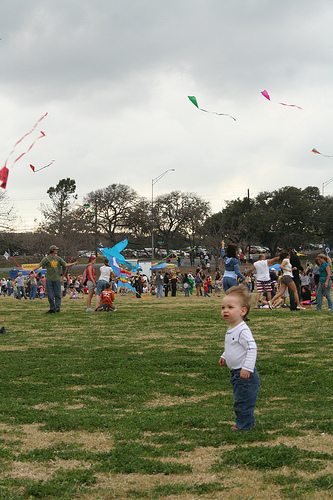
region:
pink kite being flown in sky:
[256, 87, 294, 118]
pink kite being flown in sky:
[18, 104, 49, 129]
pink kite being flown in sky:
[31, 122, 64, 151]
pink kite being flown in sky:
[36, 129, 53, 142]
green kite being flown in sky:
[177, 85, 198, 112]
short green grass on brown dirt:
[5, 408, 56, 454]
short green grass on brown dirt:
[74, 414, 137, 469]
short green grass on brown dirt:
[133, 386, 181, 421]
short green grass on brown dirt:
[114, 326, 156, 364]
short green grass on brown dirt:
[264, 428, 325, 481]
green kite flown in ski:
[183, 88, 206, 117]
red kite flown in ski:
[35, 123, 56, 150]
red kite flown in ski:
[34, 106, 51, 119]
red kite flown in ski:
[296, 133, 330, 162]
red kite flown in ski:
[252, 87, 278, 108]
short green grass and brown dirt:
[24, 338, 74, 377]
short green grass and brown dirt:
[98, 400, 157, 431]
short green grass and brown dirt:
[164, 364, 195, 414]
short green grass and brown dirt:
[270, 411, 322, 465]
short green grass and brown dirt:
[97, 455, 214, 477]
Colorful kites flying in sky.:
[171, 72, 329, 165]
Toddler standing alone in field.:
[214, 283, 262, 434]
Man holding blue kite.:
[27, 235, 140, 313]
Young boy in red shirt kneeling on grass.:
[95, 282, 116, 312]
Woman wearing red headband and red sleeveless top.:
[77, 252, 97, 287]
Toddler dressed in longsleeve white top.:
[216, 321, 259, 373]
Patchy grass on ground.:
[12, 413, 221, 499]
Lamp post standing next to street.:
[146, 163, 175, 257]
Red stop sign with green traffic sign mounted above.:
[153, 238, 167, 259]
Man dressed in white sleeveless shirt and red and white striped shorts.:
[246, 252, 277, 308]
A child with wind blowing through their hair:
[219, 285, 259, 431]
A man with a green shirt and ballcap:
[29, 245, 78, 313]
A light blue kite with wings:
[96, 239, 140, 280]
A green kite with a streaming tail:
[187, 95, 234, 120]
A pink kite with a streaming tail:
[261, 89, 301, 108]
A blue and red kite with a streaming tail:
[311, 147, 331, 157]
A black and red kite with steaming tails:
[0, 106, 47, 189]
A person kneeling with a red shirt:
[94, 282, 116, 311]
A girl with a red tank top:
[84, 256, 95, 311]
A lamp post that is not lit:
[150, 167, 173, 258]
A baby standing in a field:
[215, 285, 258, 429]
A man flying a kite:
[38, 246, 77, 314]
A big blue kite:
[97, 237, 140, 290]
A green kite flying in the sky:
[186, 93, 236, 123]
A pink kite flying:
[258, 88, 301, 108]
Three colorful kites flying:
[188, 86, 323, 155]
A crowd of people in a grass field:
[0, 242, 332, 312]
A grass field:
[0, 295, 332, 499]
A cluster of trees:
[0, 179, 332, 259]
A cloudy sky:
[0, 1, 331, 234]